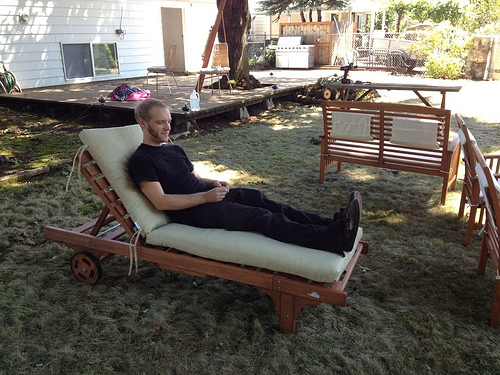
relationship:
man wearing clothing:
[127, 97, 362, 267] [131, 139, 361, 257]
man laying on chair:
[127, 97, 362, 267] [43, 92, 419, 328]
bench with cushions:
[319, 99, 463, 205] [329, 103, 459, 165]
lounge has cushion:
[35, 107, 368, 310] [140, 219, 362, 285]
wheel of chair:
[66, 251, 101, 286] [28, 150, 370, 335]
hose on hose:
[1, 59, 17, 96] [0, 59, 21, 96]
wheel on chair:
[68, 251, 101, 286] [40, 124, 378, 328]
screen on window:
[56, 37, 121, 80] [66, 43, 92, 77]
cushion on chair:
[151, 226, 356, 285] [21, 155, 381, 335]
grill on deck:
[276, 34, 318, 70] [0, 64, 352, 133]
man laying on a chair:
[129, 103, 390, 267] [40, 124, 378, 328]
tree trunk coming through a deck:
[214, 1, 284, 93] [109, 70, 246, 96]